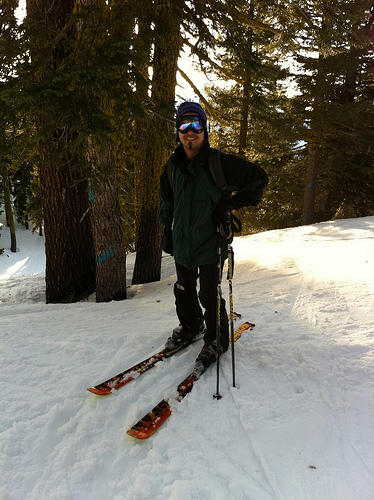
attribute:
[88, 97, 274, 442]
person — skiing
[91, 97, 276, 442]
man — standing, happily smiling, smiling, posing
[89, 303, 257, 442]
skis — orange, red, black, yellow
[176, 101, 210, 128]
hat — blue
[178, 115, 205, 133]
goggles — reflective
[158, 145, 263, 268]
jacket — thick, green, black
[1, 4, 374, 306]
trees — tall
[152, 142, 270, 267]
coat — green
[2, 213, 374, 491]
snow — clumpy, white, thick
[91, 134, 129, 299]
tree — tall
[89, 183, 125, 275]
mark — blue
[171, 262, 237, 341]
pants — black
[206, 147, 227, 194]
strap — grey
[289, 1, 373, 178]
pine needles — green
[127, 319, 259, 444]
ski — red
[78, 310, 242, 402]
ski — red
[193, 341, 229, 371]
foot — man's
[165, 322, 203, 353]
foot — man's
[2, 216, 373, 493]
ground — covered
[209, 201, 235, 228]
hand — man's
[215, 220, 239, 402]
ski poles — black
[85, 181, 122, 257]
spray paint — blue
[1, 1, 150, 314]
tree — large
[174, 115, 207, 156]
face — man's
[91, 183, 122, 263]
paint — blue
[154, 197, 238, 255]
gloves — black